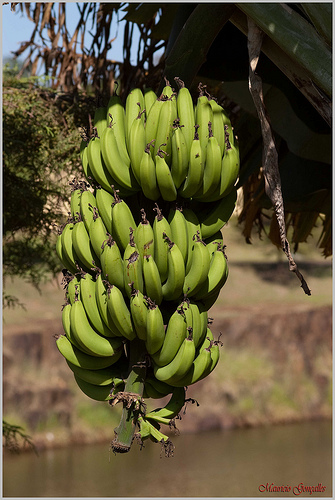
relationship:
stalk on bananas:
[112, 343, 148, 453] [50, 69, 220, 451]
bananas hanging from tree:
[54, 77, 247, 447] [147, 4, 333, 275]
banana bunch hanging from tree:
[58, 75, 237, 448] [147, 4, 333, 275]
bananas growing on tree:
[54, 77, 247, 447] [48, 58, 260, 422]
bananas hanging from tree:
[65, 70, 252, 203] [3, 3, 332, 240]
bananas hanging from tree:
[54, 77, 247, 447] [133, 6, 325, 243]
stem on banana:
[213, 332, 224, 348] [191, 346, 218, 386]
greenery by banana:
[2, 61, 85, 291] [155, 147, 177, 205]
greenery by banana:
[2, 61, 85, 291] [138, 143, 159, 200]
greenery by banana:
[2, 61, 85, 291] [178, 135, 205, 199]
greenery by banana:
[2, 61, 85, 291] [194, 130, 222, 205]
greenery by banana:
[2, 61, 85, 291] [201, 139, 239, 205]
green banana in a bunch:
[48, 76, 225, 183] [56, 82, 244, 450]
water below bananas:
[2, 417, 322, 497] [65, 65, 278, 199]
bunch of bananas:
[56, 82, 244, 450] [109, 376, 159, 445]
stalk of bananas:
[110, 405, 142, 454] [109, 376, 159, 445]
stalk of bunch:
[110, 405, 142, 454] [56, 82, 244, 450]